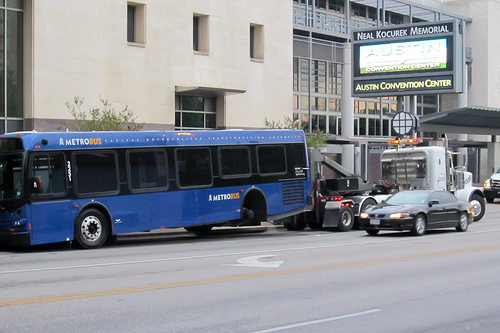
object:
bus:
[0, 130, 311, 248]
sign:
[344, 20, 466, 95]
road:
[0, 233, 500, 332]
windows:
[72, 146, 118, 196]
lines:
[6, 248, 486, 331]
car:
[359, 190, 470, 237]